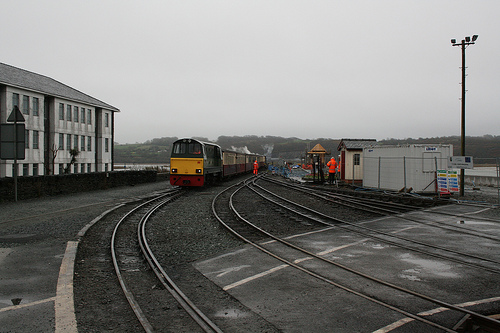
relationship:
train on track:
[168, 134, 273, 196] [107, 185, 203, 332]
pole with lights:
[459, 41, 467, 195] [448, 35, 480, 48]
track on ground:
[107, 185, 203, 332] [1, 160, 497, 326]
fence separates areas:
[0, 163, 164, 202] [3, 47, 497, 332]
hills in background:
[116, 132, 499, 164] [3, 5, 497, 219]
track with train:
[107, 185, 218, 332] [168, 134, 273, 196]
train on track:
[168, 134, 273, 196] [107, 185, 218, 332]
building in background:
[4, 60, 122, 181] [3, 5, 497, 219]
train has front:
[168, 134, 273, 196] [166, 135, 205, 189]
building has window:
[4, 60, 122, 181] [55, 132, 67, 152]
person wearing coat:
[326, 154, 340, 183] [326, 160, 337, 175]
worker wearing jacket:
[252, 156, 260, 178] [255, 158, 259, 169]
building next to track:
[4, 60, 122, 181] [107, 185, 203, 332]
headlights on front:
[172, 165, 203, 176] [166, 135, 205, 189]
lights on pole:
[448, 35, 480, 48] [459, 41, 467, 195]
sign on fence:
[434, 169, 462, 194] [361, 152, 500, 205]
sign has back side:
[1, 106, 32, 206] [1, 102, 37, 162]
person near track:
[326, 154, 340, 183] [107, 185, 203, 332]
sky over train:
[7, 2, 499, 140] [168, 134, 273, 196]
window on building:
[55, 130, 68, 152] [4, 60, 122, 181]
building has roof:
[4, 60, 122, 181] [2, 59, 122, 116]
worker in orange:
[248, 156, 261, 178] [250, 159, 260, 178]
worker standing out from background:
[248, 156, 261, 178] [3, 5, 497, 219]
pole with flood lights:
[459, 41, 467, 195] [448, 34, 479, 48]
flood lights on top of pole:
[448, 34, 479, 48] [459, 41, 467, 195]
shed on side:
[339, 134, 381, 180] [316, 116, 497, 208]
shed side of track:
[339, 134, 381, 180] [107, 185, 203, 332]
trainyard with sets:
[7, 2, 499, 323] [83, 169, 499, 322]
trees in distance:
[112, 129, 500, 165] [4, 2, 499, 206]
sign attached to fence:
[434, 169, 462, 194] [361, 152, 500, 205]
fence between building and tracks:
[0, 163, 164, 202] [3, 60, 500, 327]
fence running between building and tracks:
[0, 163, 164, 202] [3, 60, 500, 327]